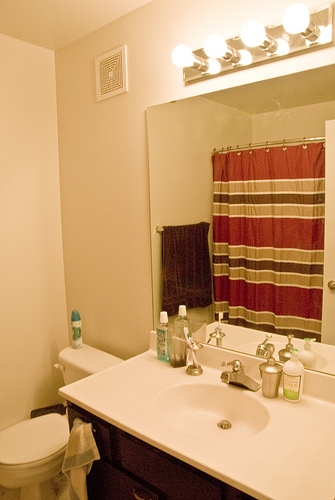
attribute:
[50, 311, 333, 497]
counter — bathroom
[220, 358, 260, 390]
fixture — steel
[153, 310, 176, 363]
bottle — mouthwash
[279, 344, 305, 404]
bottle — hand soap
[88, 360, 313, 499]
sink counter — white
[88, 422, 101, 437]
handle — drawer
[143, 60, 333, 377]
mirror — large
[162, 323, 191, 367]
cup — empty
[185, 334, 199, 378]
toothbrush holder — silver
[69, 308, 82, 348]
can — air freshener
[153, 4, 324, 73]
bulbs — studio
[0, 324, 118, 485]
toilet — white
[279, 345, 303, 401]
container — silver, soap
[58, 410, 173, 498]
cabinets — dark, wooden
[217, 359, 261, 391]
faucet — silver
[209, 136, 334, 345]
shower curtain — red, yellow, brown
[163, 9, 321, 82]
fixture — light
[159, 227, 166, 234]
rack — towel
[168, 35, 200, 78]
bulb — studio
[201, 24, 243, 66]
bulb — studio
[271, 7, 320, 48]
bulb — studio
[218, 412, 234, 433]
drain — silver